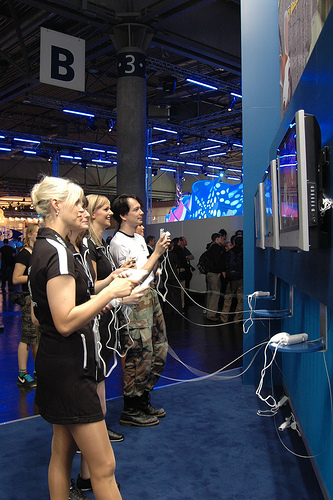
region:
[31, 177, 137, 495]
blonde woman in shorts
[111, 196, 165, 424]
man in a white shirt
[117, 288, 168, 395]
camo pants on the man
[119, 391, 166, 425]
black boots on the man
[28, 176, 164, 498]
group of people playing video games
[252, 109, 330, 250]
televisions on the wall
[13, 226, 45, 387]
woman standing behind the group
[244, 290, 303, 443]
video game controllers not being used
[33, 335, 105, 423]
black skirt on the woman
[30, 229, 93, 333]
black and white shirt on the woman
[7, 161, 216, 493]
group of four people playing a video game at a convention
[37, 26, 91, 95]
large white sign with a black B hanging from the ceiling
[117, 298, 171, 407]
man's camouflage pants with a pocket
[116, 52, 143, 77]
white number 3 on a cement pole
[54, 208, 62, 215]
silver earring a blonde lady is wearing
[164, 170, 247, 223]
large illuminated blue and pink curved sign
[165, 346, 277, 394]
white cords hanging from the video game controllers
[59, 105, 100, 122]
long neon light tube on the ceiling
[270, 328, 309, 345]
white video game device box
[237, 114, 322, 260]
three silver flat screen monitors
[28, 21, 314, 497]
the scene is in a mall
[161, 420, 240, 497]
the floor is blue in colour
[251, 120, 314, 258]
the screens are on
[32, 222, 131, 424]
the dress is black in colour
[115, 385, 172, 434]
the boots are black in colour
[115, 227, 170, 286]
the shirt is white in colour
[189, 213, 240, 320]
the men are standing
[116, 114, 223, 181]
the lights are on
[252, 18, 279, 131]
the wall is blue in colour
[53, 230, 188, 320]
the joysticks are white in colour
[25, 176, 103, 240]
the head of a woman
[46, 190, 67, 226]
the ear of a woman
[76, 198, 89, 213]
the nose of a woman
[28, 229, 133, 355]
a woman wearing a shirt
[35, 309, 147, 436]
a woman wearing a skirt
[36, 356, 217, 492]
the legs of a woman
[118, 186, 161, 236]
the head of a man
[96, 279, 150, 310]
the hand of a woman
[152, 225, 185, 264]
the hand of a man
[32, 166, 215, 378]
people playing a video game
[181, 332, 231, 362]
this is the floor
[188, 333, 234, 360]
the floor is slippery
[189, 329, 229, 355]
the floor is black in color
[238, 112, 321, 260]
these are some TVs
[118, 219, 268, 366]
these are some cables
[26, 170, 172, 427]
these are some people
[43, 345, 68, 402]
this is a dress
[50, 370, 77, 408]
the dress is black in color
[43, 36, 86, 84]
this is a board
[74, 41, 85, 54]
the board is white in color